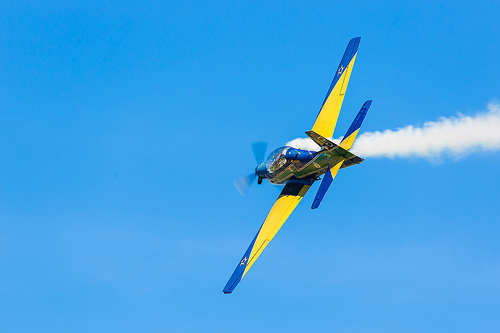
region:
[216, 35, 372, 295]
Yellow and blue aircraft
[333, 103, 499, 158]
White smoke trail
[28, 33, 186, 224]
Nice Blue sky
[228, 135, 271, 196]
Propeller of plane in motion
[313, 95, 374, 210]
Yellow and blue tail of a plane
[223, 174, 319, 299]
Yellow and blue wing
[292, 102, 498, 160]
white smoke trail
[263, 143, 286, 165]
Small windshield on plane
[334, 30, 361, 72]
Blue paint on wing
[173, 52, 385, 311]
a blue and yellow plane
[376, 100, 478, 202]
smoke coming from a plane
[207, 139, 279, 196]
propeller on a small plane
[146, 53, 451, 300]
small plane in a blue sky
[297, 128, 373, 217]
tail of a small plane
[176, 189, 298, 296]
left wing on a small plane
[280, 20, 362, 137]
right wing on a small plane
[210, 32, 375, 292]
blue and yellow stunt plane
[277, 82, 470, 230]
smoke used for skywriting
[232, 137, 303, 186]
cockpit of small stunt plane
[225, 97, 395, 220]
Plane is seen.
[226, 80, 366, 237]
plane is flying in the sky.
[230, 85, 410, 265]
Plane is blue and yellow color.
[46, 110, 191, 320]
sky is blue color.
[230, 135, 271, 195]
one propeller is seen.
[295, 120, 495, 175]
Smoke is coming out from plane.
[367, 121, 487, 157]
Smoke is white color.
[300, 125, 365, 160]
Logo is in the rear stabilizer.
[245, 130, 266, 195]
Propeller is blue color.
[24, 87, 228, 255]
No clouds seen in sky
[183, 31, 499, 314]
Plane flying with smoke coming out of it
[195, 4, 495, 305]
Blue and yellow plane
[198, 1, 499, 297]
Smoking plane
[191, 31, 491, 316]
Smoke coming out of plane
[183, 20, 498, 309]
Smoking plane in air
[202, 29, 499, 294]
Blue and yellow smoking plane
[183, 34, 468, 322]
Small blue and yellow plane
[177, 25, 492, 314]
Smokey blue and yellow plane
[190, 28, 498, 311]
Plane with blue and yellow stripes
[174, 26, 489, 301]
Flying plane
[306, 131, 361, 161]
tail wing of an aeroplane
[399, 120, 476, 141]
white smoke from the aeroplne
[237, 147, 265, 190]
front propellor of the aeroplne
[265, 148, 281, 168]
part of the pilot's cockpit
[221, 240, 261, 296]
part of the left wing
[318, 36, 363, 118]
right wing of the aeropane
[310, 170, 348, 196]
hind left wing of the aeroplane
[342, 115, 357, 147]
hind right wing of the aeroplane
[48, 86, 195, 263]
part of the blue sky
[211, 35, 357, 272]
a blue and yellow flying aeroplane